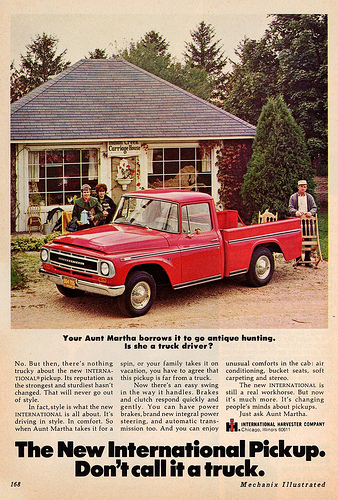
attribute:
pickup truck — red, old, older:
[40, 185, 306, 317]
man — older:
[288, 177, 319, 273]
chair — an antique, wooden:
[295, 214, 325, 270]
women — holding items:
[72, 178, 117, 227]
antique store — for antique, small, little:
[9, 58, 262, 232]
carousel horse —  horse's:
[155, 166, 197, 191]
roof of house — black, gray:
[12, 62, 257, 141]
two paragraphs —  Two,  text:
[12, 354, 329, 433]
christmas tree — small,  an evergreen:
[243, 93, 317, 216]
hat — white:
[296, 174, 308, 186]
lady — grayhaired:
[69, 180, 105, 233]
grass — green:
[314, 206, 328, 261]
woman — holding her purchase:
[93, 180, 118, 222]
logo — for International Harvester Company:
[224, 417, 326, 434]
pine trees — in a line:
[8, 3, 327, 173]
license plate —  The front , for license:
[60, 276, 77, 294]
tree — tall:
[269, 13, 329, 175]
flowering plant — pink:
[38, 151, 100, 165]